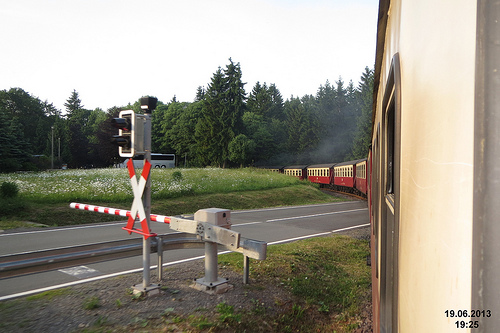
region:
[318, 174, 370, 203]
the train is on a curve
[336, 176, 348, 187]
the train is red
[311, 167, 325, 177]
the frame is cream color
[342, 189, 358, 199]
the track is rusty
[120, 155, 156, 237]
the X is on the pole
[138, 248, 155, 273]
the pole is gray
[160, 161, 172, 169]
the bus is silver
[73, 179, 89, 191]
the flowers are white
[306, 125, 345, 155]
the smoke is in the air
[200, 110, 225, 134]
the trees have green leaves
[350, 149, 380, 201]
cargo car of train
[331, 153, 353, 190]
cargo car of train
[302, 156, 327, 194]
cargo car of train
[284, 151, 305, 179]
cargo car of train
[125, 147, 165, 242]
red and white X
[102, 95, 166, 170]
traffic light on post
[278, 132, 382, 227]
long train traveling on tracks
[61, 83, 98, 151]
tall green leafy tree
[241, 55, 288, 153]
tall green leafy tree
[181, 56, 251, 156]
tall green leafy tree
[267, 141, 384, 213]
train cars on a train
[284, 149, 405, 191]
train cars on a train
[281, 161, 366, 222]
train cars on a train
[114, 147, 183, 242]
red and white x in photo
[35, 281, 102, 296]
white line painted on the ground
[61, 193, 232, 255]
red and white guard rail across road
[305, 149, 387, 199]
side photo of train cars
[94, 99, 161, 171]
traffic signal for train cars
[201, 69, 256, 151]
tall green tree in distance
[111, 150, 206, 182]
white colored public bus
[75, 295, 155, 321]
area of light brown dirt on ground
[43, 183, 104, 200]
area with white flowers on ground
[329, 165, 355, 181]
row of windows on train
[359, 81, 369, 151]
green trees behind train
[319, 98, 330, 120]
green trees behind train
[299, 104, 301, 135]
green trees behind train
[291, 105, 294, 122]
green trees behind train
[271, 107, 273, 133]
green trees behind train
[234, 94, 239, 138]
green trees behind train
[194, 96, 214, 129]
green trees behind train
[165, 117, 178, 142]
green trees behind train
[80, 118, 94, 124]
green trees behind train